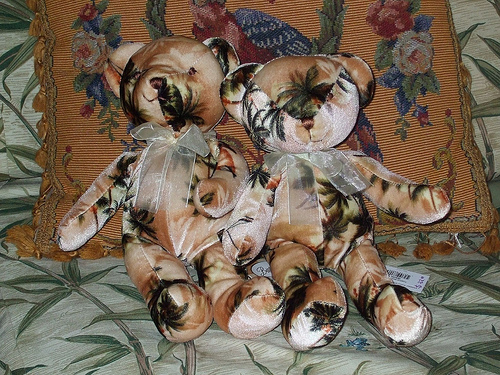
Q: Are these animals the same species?
A: Yes, all the animals are bears.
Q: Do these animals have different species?
A: No, all the animals are bears.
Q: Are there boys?
A: No, there are no boys.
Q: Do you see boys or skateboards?
A: No, there are no boys or skateboards.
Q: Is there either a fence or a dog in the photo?
A: No, there are no fences or dogs.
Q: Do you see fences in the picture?
A: No, there are no fences.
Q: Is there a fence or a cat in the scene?
A: No, there are no fences or cats.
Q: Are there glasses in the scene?
A: No, there are no glasses.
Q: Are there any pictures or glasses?
A: No, there are no glasses or pictures.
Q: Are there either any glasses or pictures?
A: No, there are no glasses or pictures.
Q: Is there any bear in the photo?
A: Yes, there is a bear.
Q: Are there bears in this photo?
A: Yes, there is a bear.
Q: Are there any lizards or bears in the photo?
A: Yes, there is a bear.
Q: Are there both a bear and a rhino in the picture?
A: No, there is a bear but no rhinos.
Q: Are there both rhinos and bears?
A: No, there is a bear but no rhinos.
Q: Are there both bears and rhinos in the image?
A: No, there is a bear but no rhinos.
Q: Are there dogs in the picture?
A: No, there are no dogs.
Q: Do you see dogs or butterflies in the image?
A: No, there are no dogs or butterflies.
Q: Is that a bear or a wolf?
A: That is a bear.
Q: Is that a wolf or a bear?
A: That is a bear.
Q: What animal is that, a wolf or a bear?
A: That is a bear.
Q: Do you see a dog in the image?
A: No, there are no dogs.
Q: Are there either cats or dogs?
A: No, there are no dogs or cats.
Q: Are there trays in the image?
A: No, there are no trays.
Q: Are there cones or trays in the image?
A: No, there are no trays or cones.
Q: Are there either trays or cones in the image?
A: No, there are no trays or cones.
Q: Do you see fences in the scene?
A: No, there are no fences.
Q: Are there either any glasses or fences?
A: No, there are no fences or glasses.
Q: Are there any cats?
A: No, there are no cats.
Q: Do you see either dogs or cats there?
A: No, there are no cats or dogs.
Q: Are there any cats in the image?
A: No, there are no cats.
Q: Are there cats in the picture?
A: No, there are no cats.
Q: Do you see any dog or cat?
A: No, there are no cats or dogs.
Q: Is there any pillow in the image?
A: Yes, there is a pillow.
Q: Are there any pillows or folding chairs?
A: Yes, there is a pillow.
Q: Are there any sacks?
A: No, there are no sacks.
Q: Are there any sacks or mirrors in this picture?
A: No, there are no sacks or mirrors.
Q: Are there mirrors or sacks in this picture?
A: No, there are no sacks or mirrors.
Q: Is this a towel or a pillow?
A: This is a pillow.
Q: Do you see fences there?
A: No, there are no fences.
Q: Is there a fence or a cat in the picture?
A: No, there are no fences or cats.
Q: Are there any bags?
A: No, there are no bags.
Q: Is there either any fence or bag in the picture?
A: No, there are no bags or fences.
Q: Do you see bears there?
A: Yes, there is a bear.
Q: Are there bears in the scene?
A: Yes, there is a bear.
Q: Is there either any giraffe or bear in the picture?
A: Yes, there is a bear.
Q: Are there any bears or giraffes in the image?
A: Yes, there is a bear.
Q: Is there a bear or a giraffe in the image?
A: Yes, there is a bear.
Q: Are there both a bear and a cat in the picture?
A: No, there is a bear but no cats.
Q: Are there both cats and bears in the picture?
A: No, there is a bear but no cats.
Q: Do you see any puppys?
A: No, there are no puppys.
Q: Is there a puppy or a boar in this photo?
A: No, there are no puppys or boars.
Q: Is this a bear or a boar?
A: This is a bear.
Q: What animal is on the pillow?
A: The bear is on the pillow.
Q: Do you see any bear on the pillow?
A: Yes, there is a bear on the pillow.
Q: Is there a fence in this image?
A: No, there are no fences.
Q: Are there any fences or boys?
A: No, there are no fences or boys.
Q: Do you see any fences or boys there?
A: No, there are no fences or boys.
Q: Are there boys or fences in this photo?
A: No, there are no fences or boys.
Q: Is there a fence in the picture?
A: No, there are no fences.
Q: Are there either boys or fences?
A: No, there are no fences or boys.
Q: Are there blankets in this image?
A: Yes, there is a blanket.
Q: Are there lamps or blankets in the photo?
A: Yes, there is a blanket.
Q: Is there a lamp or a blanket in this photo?
A: Yes, there is a blanket.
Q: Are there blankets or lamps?
A: Yes, there is a blanket.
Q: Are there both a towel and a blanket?
A: No, there is a blanket but no towels.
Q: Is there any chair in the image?
A: No, there are no chairs.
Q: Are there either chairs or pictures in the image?
A: No, there are no chairs or pictures.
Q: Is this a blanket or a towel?
A: This is a blanket.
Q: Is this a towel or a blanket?
A: This is a blanket.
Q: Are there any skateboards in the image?
A: No, there are no skateboards.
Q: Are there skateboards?
A: No, there are no skateboards.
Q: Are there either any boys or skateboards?
A: No, there are no skateboards or boys.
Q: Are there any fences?
A: No, there are no fences.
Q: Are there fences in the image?
A: No, there are no fences.